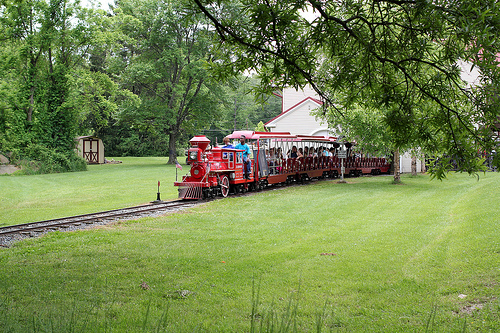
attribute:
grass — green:
[287, 203, 315, 220]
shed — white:
[71, 129, 113, 167]